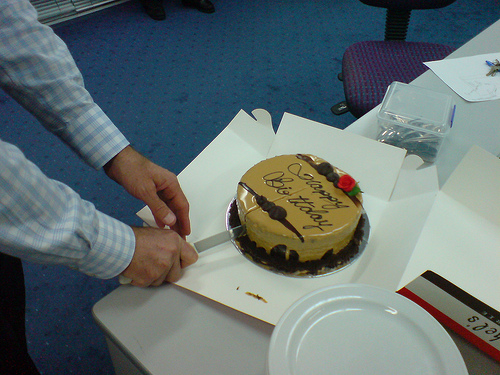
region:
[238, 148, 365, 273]
chocolate birthday cake.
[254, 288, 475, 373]
white plastic plates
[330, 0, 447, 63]
part of purple office chair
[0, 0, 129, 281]
person wearing plaid shirt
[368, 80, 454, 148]
square plastic bin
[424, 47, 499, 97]
white paper on office table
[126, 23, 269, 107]
part of blue office carpet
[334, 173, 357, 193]
red eatable flower on cake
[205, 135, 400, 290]
cake with decoration in box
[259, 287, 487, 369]
plate that is bare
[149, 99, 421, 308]
box pastry came in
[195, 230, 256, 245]
blade used to cut pastry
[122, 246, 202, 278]
handle on blade to cut pastry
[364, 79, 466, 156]
plastic container with items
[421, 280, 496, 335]
logo info on pastry box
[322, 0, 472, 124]
chair at the table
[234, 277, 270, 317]
frosting on the box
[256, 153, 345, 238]
letters on the pastry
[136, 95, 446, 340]
a cake in a box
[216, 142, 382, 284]
the cake is dark yellow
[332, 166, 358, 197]
a red rose on cake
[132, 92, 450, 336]
cake on a white box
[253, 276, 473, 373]
a dish color white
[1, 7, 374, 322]
person cutting a cake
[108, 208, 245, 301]
hand holding a knife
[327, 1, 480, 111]
a purple chair in front a desk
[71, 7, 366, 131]
the carpet is color blue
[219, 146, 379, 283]
base of cake is brown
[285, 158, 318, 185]
black letter on cake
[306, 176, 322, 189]
black letter on cake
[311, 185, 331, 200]
black letter on cake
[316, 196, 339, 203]
black letter on cake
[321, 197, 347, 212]
black letter on cake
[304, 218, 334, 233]
black letter on cake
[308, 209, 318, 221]
black letter on cake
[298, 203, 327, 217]
black letter on cake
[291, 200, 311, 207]
black letter on cake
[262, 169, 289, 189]
black letter on cake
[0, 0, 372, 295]
A person is cutting a cake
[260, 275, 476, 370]
A plate is white and round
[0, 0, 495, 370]
A blue carpet on the floor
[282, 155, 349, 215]
The word "Happy" on the cake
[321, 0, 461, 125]
A purple chair next to the table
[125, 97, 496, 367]
A cake is on a white box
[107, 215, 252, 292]
A knife in a hand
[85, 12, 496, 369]
The table is long and white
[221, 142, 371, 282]
The cake is round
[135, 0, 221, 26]
A pair of black shoes